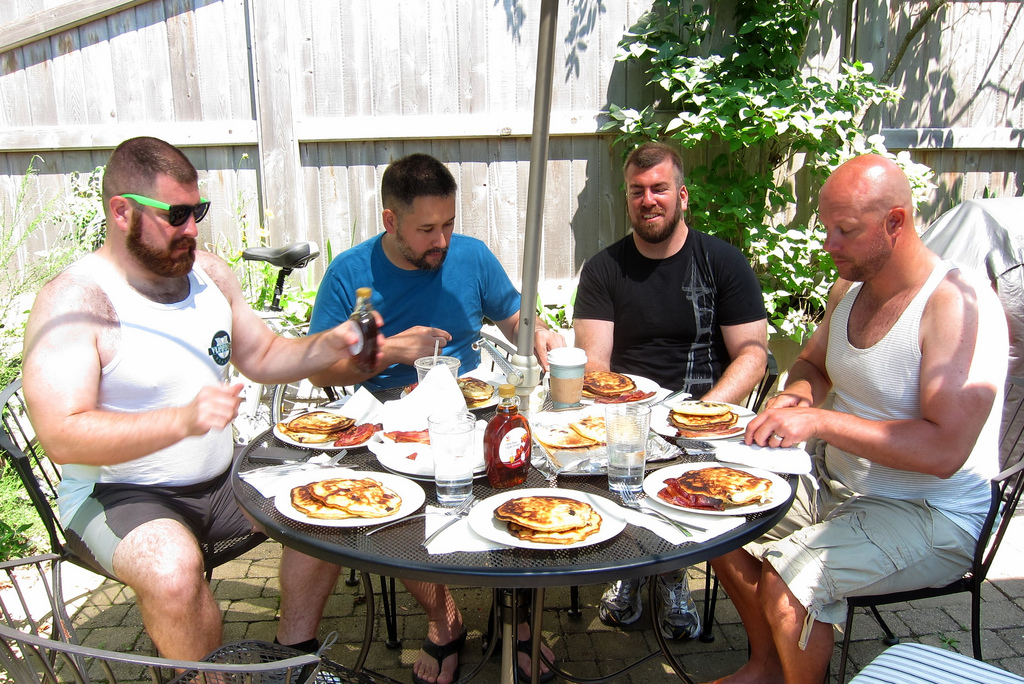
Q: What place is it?
A: It is a patio.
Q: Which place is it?
A: It is a patio.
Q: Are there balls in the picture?
A: No, there are no balls.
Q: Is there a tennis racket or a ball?
A: No, there are no balls or rackets.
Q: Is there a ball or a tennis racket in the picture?
A: No, there are no balls or rackets.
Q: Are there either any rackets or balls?
A: No, there are no balls or rackets.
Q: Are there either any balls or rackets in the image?
A: No, there are no balls or rackets.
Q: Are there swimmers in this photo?
A: No, there are no swimmers.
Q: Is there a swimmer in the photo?
A: No, there are no swimmers.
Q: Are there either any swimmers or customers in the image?
A: No, there are no swimmers or customers.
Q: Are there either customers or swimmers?
A: No, there are no swimmers or customers.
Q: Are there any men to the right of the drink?
A: Yes, there is a man to the right of the drink.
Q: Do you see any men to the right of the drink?
A: Yes, there is a man to the right of the drink.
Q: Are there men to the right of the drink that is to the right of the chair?
A: Yes, there is a man to the right of the drink.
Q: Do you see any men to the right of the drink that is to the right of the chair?
A: Yes, there is a man to the right of the drink.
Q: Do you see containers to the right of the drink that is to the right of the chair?
A: No, there is a man to the right of the drink.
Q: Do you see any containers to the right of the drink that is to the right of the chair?
A: No, there is a man to the right of the drink.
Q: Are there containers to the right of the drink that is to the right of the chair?
A: No, there is a man to the right of the drink.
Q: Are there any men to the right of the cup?
A: Yes, there is a man to the right of the cup.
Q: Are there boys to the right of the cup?
A: No, there is a man to the right of the cup.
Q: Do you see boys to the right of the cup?
A: No, there is a man to the right of the cup.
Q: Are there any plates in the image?
A: Yes, there is a plate.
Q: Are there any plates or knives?
A: Yes, there is a plate.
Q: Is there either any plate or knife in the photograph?
A: Yes, there is a plate.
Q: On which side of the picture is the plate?
A: The plate is on the right of the image.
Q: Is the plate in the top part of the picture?
A: No, the plate is in the bottom of the image.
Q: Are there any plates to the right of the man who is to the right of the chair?
A: Yes, there is a plate to the right of the man.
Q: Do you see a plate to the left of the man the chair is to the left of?
A: No, the plate is to the right of the man.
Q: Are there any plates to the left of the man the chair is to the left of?
A: No, the plate is to the right of the man.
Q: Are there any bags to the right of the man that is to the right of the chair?
A: No, there is a plate to the right of the man.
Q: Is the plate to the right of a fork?
A: No, the plate is to the right of a man.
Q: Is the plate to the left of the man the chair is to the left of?
A: No, the plate is to the right of the man.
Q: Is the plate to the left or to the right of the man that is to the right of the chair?
A: The plate is to the right of the man.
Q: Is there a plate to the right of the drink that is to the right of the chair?
A: Yes, there is a plate to the right of the drink.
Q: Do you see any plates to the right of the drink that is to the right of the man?
A: Yes, there is a plate to the right of the drink.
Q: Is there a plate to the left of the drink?
A: No, the plate is to the right of the drink.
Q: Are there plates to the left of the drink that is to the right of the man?
A: No, the plate is to the right of the drink.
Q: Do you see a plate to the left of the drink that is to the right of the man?
A: No, the plate is to the right of the drink.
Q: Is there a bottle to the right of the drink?
A: No, there is a plate to the right of the drink.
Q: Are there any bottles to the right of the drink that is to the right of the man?
A: No, there is a plate to the right of the drink.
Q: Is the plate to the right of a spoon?
A: No, the plate is to the right of the drink.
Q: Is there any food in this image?
A: Yes, there is food.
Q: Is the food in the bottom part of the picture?
A: Yes, the food is in the bottom of the image.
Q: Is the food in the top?
A: No, the food is in the bottom of the image.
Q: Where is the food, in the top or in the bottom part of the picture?
A: The food is in the bottom of the image.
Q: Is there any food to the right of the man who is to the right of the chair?
A: Yes, there is food to the right of the man.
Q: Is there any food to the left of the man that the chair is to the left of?
A: No, the food is to the right of the man.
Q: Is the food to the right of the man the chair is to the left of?
A: Yes, the food is to the right of the man.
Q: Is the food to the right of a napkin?
A: No, the food is to the right of the man.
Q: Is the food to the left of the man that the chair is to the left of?
A: No, the food is to the right of the man.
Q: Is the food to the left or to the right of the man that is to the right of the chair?
A: The food is to the right of the man.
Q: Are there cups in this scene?
A: Yes, there is a cup.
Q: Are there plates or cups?
A: Yes, there is a cup.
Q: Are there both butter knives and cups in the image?
A: No, there is a cup but no butter knives.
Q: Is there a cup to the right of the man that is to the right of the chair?
A: Yes, there is a cup to the right of the man.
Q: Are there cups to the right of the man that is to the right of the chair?
A: Yes, there is a cup to the right of the man.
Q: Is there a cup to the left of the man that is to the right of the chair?
A: No, the cup is to the right of the man.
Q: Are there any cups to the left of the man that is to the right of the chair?
A: No, the cup is to the right of the man.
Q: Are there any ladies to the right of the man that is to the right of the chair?
A: No, there is a cup to the right of the man.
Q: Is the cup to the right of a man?
A: Yes, the cup is to the right of a man.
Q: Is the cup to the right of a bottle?
A: No, the cup is to the right of a man.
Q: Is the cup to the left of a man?
A: No, the cup is to the right of a man.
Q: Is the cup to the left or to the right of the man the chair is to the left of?
A: The cup is to the right of the man.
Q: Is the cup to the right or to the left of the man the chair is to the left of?
A: The cup is to the right of the man.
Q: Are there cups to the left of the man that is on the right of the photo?
A: Yes, there is a cup to the left of the man.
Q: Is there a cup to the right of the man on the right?
A: No, the cup is to the left of the man.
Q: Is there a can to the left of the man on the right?
A: No, there is a cup to the left of the man.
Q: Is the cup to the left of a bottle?
A: No, the cup is to the left of the man.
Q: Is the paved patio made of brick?
A: Yes, the patio is made of brick.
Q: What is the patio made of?
A: The patio is made of brick.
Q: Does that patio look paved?
A: Yes, the patio is paved.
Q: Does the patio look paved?
A: Yes, the patio is paved.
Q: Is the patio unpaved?
A: No, the patio is paved.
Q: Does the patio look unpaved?
A: No, the patio is paved.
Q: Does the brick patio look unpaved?
A: No, the patio is paved.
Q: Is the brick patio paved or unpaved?
A: The patio is paved.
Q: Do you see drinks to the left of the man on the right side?
A: Yes, there is a drink to the left of the man.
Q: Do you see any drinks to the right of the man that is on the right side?
A: No, the drink is to the left of the man.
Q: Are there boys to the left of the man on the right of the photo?
A: No, there is a drink to the left of the man.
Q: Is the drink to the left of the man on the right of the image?
A: Yes, the drink is to the left of the man.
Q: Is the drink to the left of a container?
A: No, the drink is to the left of the man.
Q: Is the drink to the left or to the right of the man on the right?
A: The drink is to the left of the man.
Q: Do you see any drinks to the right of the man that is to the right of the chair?
A: Yes, there is a drink to the right of the man.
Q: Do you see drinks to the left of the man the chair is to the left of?
A: No, the drink is to the right of the man.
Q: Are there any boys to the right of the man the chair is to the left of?
A: No, there is a drink to the right of the man.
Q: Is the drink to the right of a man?
A: Yes, the drink is to the right of a man.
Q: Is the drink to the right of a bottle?
A: No, the drink is to the right of a man.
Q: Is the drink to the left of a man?
A: No, the drink is to the right of a man.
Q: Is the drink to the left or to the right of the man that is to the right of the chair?
A: The drink is to the right of the man.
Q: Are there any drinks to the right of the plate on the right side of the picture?
A: No, the drink is to the left of the plate.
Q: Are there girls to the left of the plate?
A: No, there is a drink to the left of the plate.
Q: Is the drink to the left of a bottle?
A: No, the drink is to the left of the plate.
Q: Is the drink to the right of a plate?
A: No, the drink is to the left of a plate.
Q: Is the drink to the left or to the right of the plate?
A: The drink is to the left of the plate.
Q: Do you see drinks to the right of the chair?
A: Yes, there is a drink to the right of the chair.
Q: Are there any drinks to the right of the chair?
A: Yes, there is a drink to the right of the chair.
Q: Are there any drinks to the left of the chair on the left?
A: No, the drink is to the right of the chair.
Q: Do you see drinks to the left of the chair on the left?
A: No, the drink is to the right of the chair.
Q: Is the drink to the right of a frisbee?
A: No, the drink is to the right of the chair.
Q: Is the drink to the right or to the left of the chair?
A: The drink is to the right of the chair.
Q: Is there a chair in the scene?
A: Yes, there is a chair.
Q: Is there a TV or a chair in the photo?
A: Yes, there is a chair.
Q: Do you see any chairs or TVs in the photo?
A: Yes, there is a chair.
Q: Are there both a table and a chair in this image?
A: Yes, there are both a chair and a table.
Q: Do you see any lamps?
A: No, there are no lamps.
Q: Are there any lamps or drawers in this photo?
A: No, there are no lamps or drawers.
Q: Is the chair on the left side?
A: Yes, the chair is on the left of the image.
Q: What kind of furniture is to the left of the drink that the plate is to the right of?
A: The piece of furniture is a chair.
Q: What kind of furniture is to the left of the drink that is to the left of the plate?
A: The piece of furniture is a chair.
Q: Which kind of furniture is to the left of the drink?
A: The piece of furniture is a chair.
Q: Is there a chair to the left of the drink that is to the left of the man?
A: Yes, there is a chair to the left of the drink.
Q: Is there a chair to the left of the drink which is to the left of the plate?
A: Yes, there is a chair to the left of the drink.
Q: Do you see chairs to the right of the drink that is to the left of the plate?
A: No, the chair is to the left of the drink.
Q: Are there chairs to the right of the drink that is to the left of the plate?
A: No, the chair is to the left of the drink.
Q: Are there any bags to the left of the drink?
A: No, there is a chair to the left of the drink.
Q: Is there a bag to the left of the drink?
A: No, there is a chair to the left of the drink.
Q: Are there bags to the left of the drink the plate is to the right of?
A: No, there is a chair to the left of the drink.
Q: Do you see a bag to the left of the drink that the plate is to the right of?
A: No, there is a chair to the left of the drink.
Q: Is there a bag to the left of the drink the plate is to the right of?
A: No, there is a chair to the left of the drink.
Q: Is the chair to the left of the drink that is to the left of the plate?
A: Yes, the chair is to the left of the drink.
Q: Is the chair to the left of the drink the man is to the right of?
A: Yes, the chair is to the left of the drink.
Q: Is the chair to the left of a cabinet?
A: No, the chair is to the left of the drink.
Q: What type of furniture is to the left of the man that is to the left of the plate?
A: The piece of furniture is a chair.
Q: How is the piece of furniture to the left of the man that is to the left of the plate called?
A: The piece of furniture is a chair.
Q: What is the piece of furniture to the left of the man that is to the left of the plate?
A: The piece of furniture is a chair.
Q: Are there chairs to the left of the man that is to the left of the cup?
A: Yes, there is a chair to the left of the man.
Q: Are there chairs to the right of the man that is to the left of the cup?
A: No, the chair is to the left of the man.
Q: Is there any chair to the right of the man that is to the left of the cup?
A: No, the chair is to the left of the man.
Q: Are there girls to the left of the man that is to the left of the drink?
A: No, there is a chair to the left of the man.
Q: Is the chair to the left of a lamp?
A: No, the chair is to the left of the man.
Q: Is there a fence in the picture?
A: Yes, there is a fence.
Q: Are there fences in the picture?
A: Yes, there is a fence.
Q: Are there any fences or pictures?
A: Yes, there is a fence.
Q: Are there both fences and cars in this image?
A: No, there is a fence but no cars.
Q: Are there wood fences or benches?
A: Yes, there is a wood fence.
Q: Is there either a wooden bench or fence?
A: Yes, there is a wood fence.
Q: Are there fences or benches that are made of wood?
A: Yes, the fence is made of wood.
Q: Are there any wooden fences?
A: Yes, there is a wood fence.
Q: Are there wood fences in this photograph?
A: Yes, there is a wood fence.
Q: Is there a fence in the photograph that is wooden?
A: Yes, there is a fence that is wooden.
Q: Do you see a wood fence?
A: Yes, there is a fence that is made of wood.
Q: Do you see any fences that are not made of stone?
A: Yes, there is a fence that is made of wood.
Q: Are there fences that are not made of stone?
A: Yes, there is a fence that is made of wood.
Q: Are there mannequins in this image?
A: No, there are no mannequins.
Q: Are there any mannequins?
A: No, there are no mannequins.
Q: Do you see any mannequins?
A: No, there are no mannequins.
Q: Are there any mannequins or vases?
A: No, there are no mannequins or vases.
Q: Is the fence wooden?
A: Yes, the fence is wooden.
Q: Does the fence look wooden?
A: Yes, the fence is wooden.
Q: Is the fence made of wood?
A: Yes, the fence is made of wood.